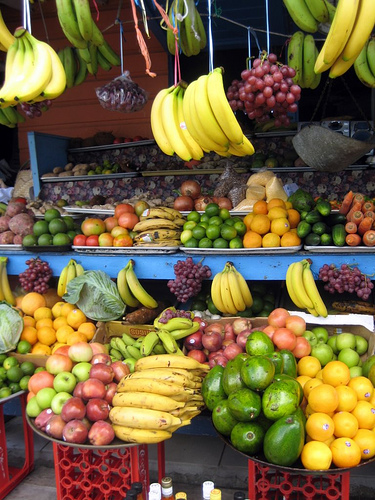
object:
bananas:
[207, 65, 245, 146]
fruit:
[329, 436, 364, 470]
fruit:
[204, 202, 219, 218]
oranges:
[297, 355, 322, 378]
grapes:
[194, 270, 200, 280]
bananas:
[228, 264, 247, 312]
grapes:
[29, 271, 36, 280]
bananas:
[56, 260, 70, 298]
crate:
[49, 440, 164, 500]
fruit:
[79, 375, 107, 402]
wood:
[0, 251, 374, 282]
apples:
[201, 329, 223, 352]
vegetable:
[66, 270, 127, 322]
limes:
[6, 365, 24, 383]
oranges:
[36, 325, 57, 347]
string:
[170, 11, 184, 88]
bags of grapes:
[96, 70, 148, 113]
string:
[114, 17, 125, 77]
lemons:
[261, 231, 280, 247]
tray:
[230, 201, 254, 215]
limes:
[220, 223, 238, 241]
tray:
[179, 243, 304, 257]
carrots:
[344, 232, 361, 246]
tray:
[303, 242, 375, 256]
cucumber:
[317, 199, 332, 216]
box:
[88, 320, 165, 342]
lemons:
[37, 325, 57, 346]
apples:
[87, 419, 115, 446]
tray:
[24, 408, 143, 449]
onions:
[5, 195, 26, 217]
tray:
[209, 417, 374, 476]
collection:
[1, 143, 374, 472]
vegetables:
[339, 189, 353, 214]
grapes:
[289, 83, 301, 97]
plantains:
[73, 0, 94, 42]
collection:
[0, 0, 375, 163]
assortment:
[27, 342, 128, 450]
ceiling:
[1, 1, 375, 53]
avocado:
[51, 231, 70, 246]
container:
[21, 244, 74, 254]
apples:
[59, 395, 86, 422]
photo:
[1, 1, 374, 498]